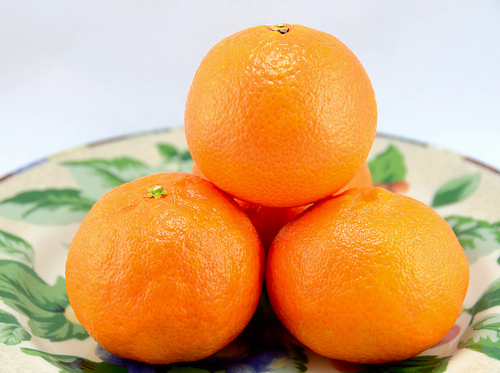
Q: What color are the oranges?
A: Orange.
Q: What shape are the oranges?
A: Round.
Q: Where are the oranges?
A: On a plate.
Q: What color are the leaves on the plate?
A: Green.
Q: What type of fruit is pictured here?
A: Oranges.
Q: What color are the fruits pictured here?
A: Orange.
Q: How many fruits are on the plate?
A: Four.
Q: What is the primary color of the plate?
A: White.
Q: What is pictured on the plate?
A: Leaves.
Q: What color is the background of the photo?
A: White.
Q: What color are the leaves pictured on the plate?
A: Green.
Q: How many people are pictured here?
A: Zero.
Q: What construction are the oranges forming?
A: Pyramid.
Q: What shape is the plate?
A: Round.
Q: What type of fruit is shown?
A: Oranges.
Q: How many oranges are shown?
A: 4.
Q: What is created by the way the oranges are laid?
A: Pyramid.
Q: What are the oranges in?
A: Plate.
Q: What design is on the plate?
A: Floral.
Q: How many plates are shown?
A: 1.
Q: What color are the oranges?
A: Orange.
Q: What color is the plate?
A: White, green, and pink.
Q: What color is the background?
A: White.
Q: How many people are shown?
A: 0.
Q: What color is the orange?
A: Orange.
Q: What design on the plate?
A: Leaves.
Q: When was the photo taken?
A: Last week.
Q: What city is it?
A: Boston.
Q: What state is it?
A: Massachusetts.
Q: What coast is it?
A: East Coast.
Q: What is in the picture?
A: Oranges.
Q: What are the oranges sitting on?
A: A plate.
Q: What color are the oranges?
A: Orange.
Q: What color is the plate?
A: Green and white.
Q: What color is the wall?
A: White.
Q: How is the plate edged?
A: In blue.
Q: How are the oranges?
A: Fresh.